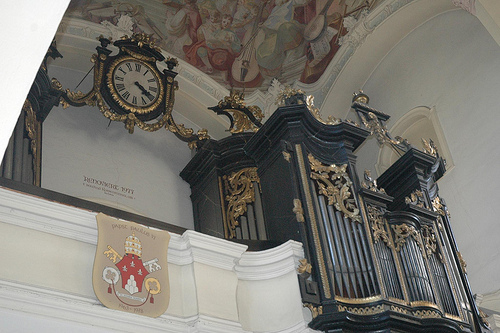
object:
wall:
[152, 246, 302, 331]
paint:
[256, 238, 305, 271]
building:
[0, 2, 498, 332]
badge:
[93, 217, 169, 315]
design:
[308, 153, 363, 225]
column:
[244, 89, 384, 331]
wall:
[446, 17, 496, 314]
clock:
[90, 30, 181, 134]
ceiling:
[195, 9, 356, 73]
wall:
[49, 134, 175, 211]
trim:
[88, 34, 113, 81]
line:
[287, 142, 370, 306]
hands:
[135, 81, 151, 96]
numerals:
[114, 62, 158, 105]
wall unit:
[179, 88, 484, 333]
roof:
[163, 0, 361, 55]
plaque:
[93, 213, 171, 318]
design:
[158, 0, 390, 51]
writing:
[76, 171, 142, 203]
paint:
[368, 0, 494, 103]